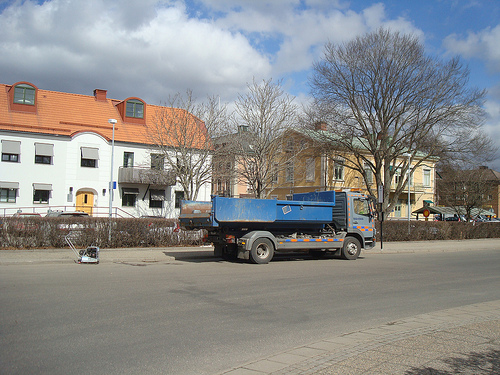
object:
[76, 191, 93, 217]
yellow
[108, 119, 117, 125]
lantern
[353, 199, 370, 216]
front window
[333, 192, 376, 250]
cab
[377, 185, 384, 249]
sign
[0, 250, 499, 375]
road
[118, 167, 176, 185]
balcony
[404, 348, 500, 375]
shadow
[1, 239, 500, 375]
sidewalk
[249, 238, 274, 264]
tire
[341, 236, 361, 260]
tire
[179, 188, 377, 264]
dumptruck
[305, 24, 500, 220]
tree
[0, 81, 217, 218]
apartment